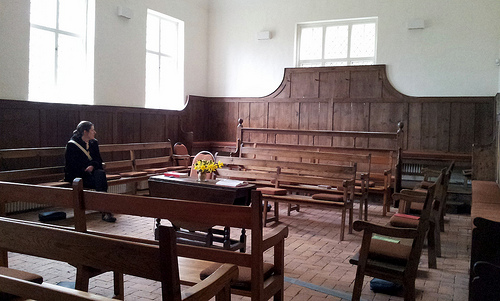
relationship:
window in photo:
[30, 4, 105, 104] [5, 20, 497, 301]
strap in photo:
[63, 140, 91, 157] [5, 20, 497, 301]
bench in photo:
[6, 135, 182, 185] [5, 20, 497, 301]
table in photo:
[147, 163, 252, 211] [5, 20, 497, 301]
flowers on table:
[193, 153, 226, 175] [147, 163, 252, 211]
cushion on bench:
[120, 168, 150, 183] [6, 135, 182, 185]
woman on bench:
[62, 109, 113, 208] [6, 135, 182, 185]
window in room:
[30, 4, 105, 104] [7, 11, 495, 165]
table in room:
[147, 163, 252, 211] [7, 11, 495, 165]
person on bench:
[70, 116, 109, 161] [6, 135, 182, 185]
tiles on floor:
[285, 218, 353, 287] [290, 207, 364, 288]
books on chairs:
[377, 209, 414, 252] [366, 194, 467, 300]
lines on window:
[36, 21, 92, 43] [30, 4, 105, 104]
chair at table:
[352, 180, 427, 300] [147, 163, 252, 211]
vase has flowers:
[200, 170, 213, 184] [193, 153, 226, 175]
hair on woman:
[66, 119, 88, 143] [62, 109, 113, 208]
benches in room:
[145, 118, 442, 204] [7, 11, 495, 165]